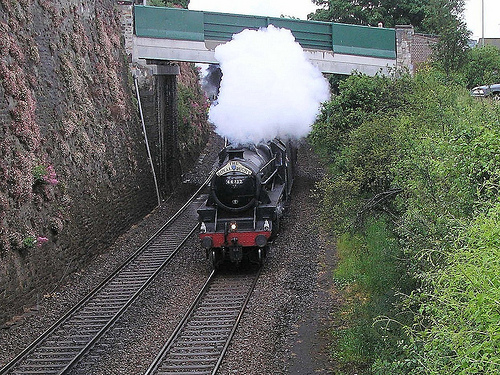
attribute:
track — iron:
[31, 165, 348, 370]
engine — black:
[192, 132, 296, 279]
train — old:
[174, 105, 319, 302]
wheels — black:
[206, 247, 268, 273]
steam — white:
[206, 25, 332, 150]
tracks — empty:
[74, 273, 285, 373]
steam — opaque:
[195, 29, 362, 153]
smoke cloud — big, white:
[210, 29, 328, 145]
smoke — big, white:
[224, 43, 322, 128]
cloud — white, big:
[215, 39, 323, 124]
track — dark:
[141, 267, 265, 374]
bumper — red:
[202, 217, 292, 261]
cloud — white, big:
[205, 20, 334, 145]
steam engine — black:
[174, 60, 321, 258]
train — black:
[192, 126, 301, 268]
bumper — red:
[204, 228, 266, 248]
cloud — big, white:
[195, 26, 314, 133]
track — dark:
[2, 234, 197, 371]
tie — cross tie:
[65, 312, 115, 321]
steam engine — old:
[195, 132, 298, 274]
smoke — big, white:
[206, 25, 330, 142]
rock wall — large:
[8, 20, 148, 239]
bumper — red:
[195, 223, 272, 253]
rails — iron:
[1, 92, 286, 370]